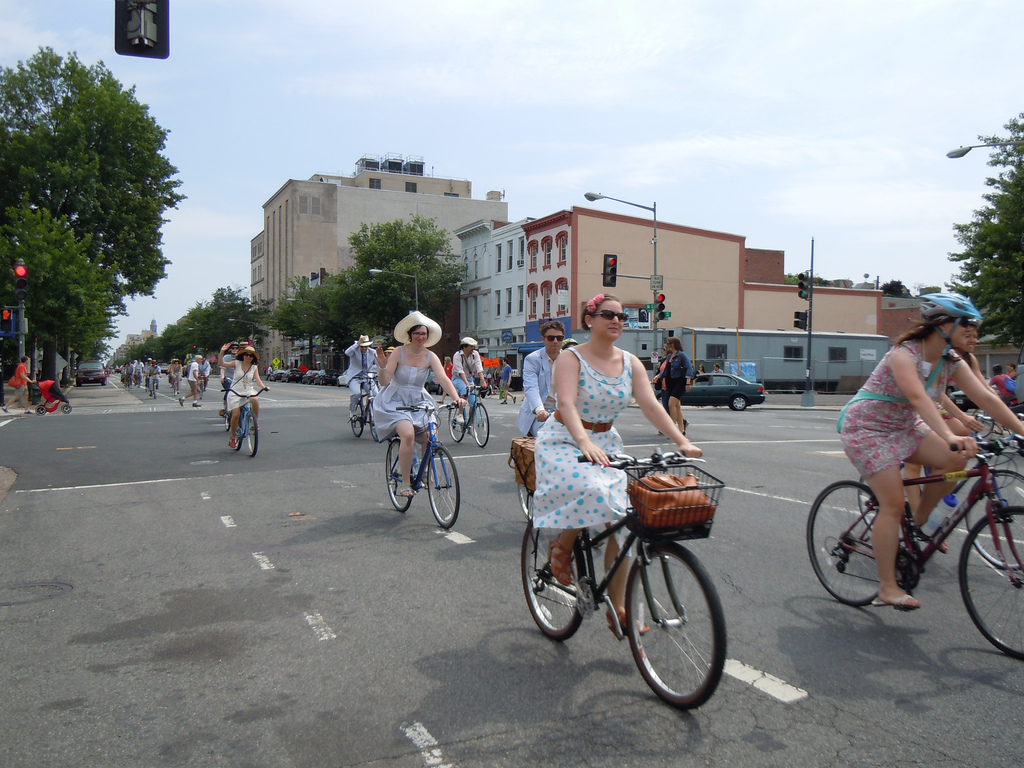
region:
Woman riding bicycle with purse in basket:
[509, 292, 738, 719]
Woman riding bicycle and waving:
[365, 310, 463, 526]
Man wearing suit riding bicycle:
[336, 329, 388, 440]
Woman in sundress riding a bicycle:
[361, 307, 461, 527]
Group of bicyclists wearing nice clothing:
[114, 289, 1016, 714]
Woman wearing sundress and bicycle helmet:
[803, 282, 1018, 663]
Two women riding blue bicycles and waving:
[207, 305, 463, 521]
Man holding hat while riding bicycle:
[337, 330, 394, 447]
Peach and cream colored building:
[518, 204, 886, 397]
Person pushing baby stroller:
[2, 355, 78, 417]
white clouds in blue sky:
[236, 43, 364, 124]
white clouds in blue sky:
[661, 104, 731, 144]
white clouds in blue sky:
[491, 116, 581, 180]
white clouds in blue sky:
[389, 0, 491, 58]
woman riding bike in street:
[507, 276, 739, 710]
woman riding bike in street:
[782, 248, 1005, 632]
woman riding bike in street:
[296, 279, 470, 520]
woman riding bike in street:
[204, 323, 277, 451]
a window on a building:
[496, 236, 501, 282]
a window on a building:
[510, 233, 533, 275]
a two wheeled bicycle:
[495, 417, 746, 735]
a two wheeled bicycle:
[811, 398, 1021, 627]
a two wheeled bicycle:
[343, 399, 465, 526]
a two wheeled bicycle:
[425, 361, 503, 448]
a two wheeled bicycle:
[214, 388, 272, 464]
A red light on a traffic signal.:
[5, 252, 40, 415]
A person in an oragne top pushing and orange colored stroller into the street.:
[2, 357, 76, 421]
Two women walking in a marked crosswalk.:
[640, 322, 713, 458]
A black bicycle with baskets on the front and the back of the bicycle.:
[506, 429, 728, 714]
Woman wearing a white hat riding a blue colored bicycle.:
[374, 303, 466, 544]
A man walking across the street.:
[175, 350, 218, 420]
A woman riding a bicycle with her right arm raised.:
[213, 337, 272, 465]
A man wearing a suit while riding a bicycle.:
[333, 329, 385, 448]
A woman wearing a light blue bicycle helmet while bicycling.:
[808, 287, 1021, 673]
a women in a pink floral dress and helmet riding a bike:
[800, 288, 1022, 656]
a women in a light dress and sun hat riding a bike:
[365, 309, 464, 532]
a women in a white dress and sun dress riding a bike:
[204, 337, 274, 458]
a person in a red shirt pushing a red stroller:
[2, 350, 75, 424]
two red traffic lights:
[593, 243, 670, 341]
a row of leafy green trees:
[114, 217, 465, 367]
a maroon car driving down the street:
[65, 356, 113, 394]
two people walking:
[646, 335, 697, 431]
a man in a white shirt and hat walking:
[166, 350, 211, 415]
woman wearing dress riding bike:
[471, 289, 766, 720]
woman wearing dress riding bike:
[808, 273, 1011, 656]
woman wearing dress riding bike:
[218, 338, 275, 465]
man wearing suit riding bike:
[335, 326, 377, 434]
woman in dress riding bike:
[373, 331, 468, 467]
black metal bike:
[501, 462, 745, 713]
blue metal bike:
[365, 414, 467, 526]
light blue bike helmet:
[896, 288, 986, 340]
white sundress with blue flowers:
[536, 348, 692, 560]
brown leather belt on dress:
[547, 413, 625, 445]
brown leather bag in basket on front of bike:
[637, 462, 724, 546]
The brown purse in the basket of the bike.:
[635, 464, 711, 529]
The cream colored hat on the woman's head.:
[396, 315, 447, 344]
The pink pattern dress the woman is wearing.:
[846, 337, 948, 468]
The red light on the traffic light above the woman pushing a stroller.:
[7, 251, 28, 290]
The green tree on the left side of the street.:
[1, 43, 170, 388]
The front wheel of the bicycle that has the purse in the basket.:
[621, 531, 726, 705]